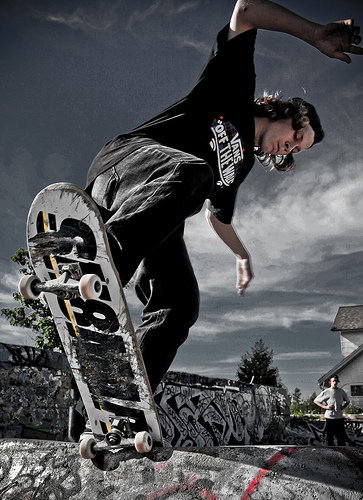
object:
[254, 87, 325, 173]
hair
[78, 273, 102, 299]
wheel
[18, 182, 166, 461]
skateboard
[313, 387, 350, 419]
shirt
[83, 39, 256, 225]
shirt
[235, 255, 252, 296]
hand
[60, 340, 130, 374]
letter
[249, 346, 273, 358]
needles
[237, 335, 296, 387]
tree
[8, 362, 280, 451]
side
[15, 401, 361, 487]
ramp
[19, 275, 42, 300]
wheels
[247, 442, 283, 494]
line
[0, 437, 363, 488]
ground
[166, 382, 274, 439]
graffiti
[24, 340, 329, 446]
wall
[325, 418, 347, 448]
jeans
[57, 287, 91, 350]
line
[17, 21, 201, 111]
sky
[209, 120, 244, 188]
letters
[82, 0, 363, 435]
guy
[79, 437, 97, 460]
wheels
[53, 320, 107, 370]
scuffs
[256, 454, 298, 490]
paint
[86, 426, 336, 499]
concrete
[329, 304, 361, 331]
roof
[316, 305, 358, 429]
home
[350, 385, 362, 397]
window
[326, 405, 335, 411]
hands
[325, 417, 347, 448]
pants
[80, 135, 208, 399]
jeans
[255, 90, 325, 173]
head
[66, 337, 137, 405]
scraping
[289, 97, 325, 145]
hat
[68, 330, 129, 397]
scratches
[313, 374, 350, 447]
guy